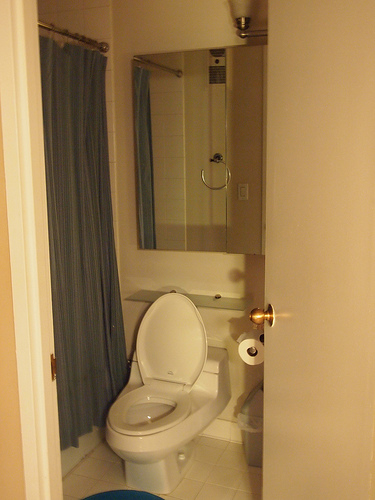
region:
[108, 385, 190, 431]
the white toilet seat cover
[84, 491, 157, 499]
the blue bath mat on the floor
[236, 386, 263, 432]
the clear plastic trash bag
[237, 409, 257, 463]
the grey small trash can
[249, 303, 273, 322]
the brass colored round doorknob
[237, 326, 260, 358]
the white roll of toilet paper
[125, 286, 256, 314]
the glass shelf on the wall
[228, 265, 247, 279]
the shadow of the doorknob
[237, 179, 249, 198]
the white light switch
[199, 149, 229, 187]
the silver towel ring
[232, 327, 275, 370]
Roll of white toilet paper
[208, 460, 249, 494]
Small white tile on floor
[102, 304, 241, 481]
Large white toulet with lid up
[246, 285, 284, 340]
Small golden door handle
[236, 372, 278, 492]
Small gray trash van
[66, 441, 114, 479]
Small white tile on floor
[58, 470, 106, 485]
Small white tile on floor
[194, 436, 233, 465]
Small white tile on floor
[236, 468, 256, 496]
Small white tile on floor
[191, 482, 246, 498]
Small white tile on floor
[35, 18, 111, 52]
A shower curtain rod.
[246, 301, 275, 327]
A brass door knob.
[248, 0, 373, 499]
The door of a bathroom.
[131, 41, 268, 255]
A mirror in the bathroom.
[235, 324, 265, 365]
A white toilet paper roll.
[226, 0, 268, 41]
A light fixture in the bathroom.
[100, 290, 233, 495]
A white open toilet.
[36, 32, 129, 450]
A shower curtain in the bathroom.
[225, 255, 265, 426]
A shadow on the wall.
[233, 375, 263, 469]
A garbage can on the floor.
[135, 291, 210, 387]
toilet seat lid up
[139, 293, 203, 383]
white toilet lid in room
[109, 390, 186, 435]
white toilet seat down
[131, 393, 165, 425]
white bowl of toilet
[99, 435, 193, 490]
white base of toilet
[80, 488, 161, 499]
blue mat on ground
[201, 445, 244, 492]
white tile in bathroom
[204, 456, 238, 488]
white square tile in room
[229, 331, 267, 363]
white toilet paper in room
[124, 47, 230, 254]
mirror on wall in bathroom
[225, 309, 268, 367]
White roll of toilet paper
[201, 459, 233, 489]
Small white tile on floor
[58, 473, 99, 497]
Small white tile on floor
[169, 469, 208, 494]
Small white tile on floor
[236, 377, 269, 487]
Small grey trash can on floor